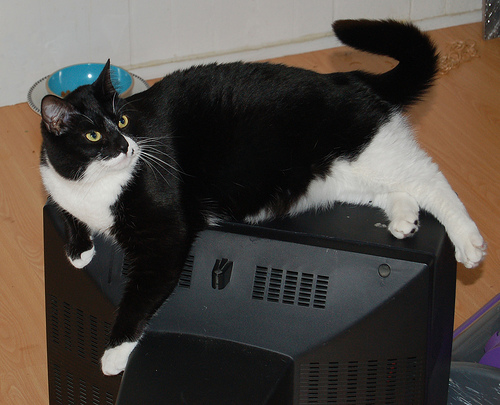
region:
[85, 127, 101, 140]
right eye of a cat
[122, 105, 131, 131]
left eye of a cat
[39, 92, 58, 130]
right ear of a cat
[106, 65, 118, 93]
left ear of a cat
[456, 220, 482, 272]
left paw of a cat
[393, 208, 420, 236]
right paw of a cat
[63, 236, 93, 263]
front right paw of a cat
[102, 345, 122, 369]
left front paw of a cat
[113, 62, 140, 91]
part of a bowl and a plate on the floor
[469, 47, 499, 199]
section of the floor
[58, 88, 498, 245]
the cat is black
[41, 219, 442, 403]
the tv is black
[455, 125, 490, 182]
the floor is is brown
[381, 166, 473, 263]
the legs are white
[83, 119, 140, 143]
the eyes are yellow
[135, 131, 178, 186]
the whiskers are white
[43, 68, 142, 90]
the bowl is blue inside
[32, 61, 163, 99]
the plate is white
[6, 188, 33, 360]
the floor is made of wood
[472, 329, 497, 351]
the clothing is purple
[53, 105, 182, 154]
Cat with green eyes.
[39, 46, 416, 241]
Cat laying down.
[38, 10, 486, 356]
Cat laying on a television set.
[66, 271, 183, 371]
Cat's white paw on the television.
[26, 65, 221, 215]
Cat's white whiskers.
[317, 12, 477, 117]
Cat's black tail.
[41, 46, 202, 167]
Blue bowl behind cat.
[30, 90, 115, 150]
Cat is looking around.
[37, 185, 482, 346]
Black television set.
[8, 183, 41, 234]
Television set on the floor.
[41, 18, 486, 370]
a black and white cat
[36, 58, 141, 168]
the cat's head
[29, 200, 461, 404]
a black television set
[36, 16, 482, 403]
a cat on top of the television set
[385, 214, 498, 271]
the cat's white paws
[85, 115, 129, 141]
the cat's eyes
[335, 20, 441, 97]
the cat's black tail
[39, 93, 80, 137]
the cat's ear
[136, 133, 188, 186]
the cat's white whiskers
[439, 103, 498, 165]
part of the floor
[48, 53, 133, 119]
Blue food bowl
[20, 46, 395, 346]
Cat on TV set.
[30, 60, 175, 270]
Black and white cat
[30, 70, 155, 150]
Yellow eyes watching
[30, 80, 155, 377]
Front paws with white mittens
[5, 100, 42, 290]
Wood look table top.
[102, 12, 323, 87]
White wall behind cat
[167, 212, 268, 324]
Mount for exterior anntena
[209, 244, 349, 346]
Vents on TV for cooling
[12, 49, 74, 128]
Plate holds kibble bowl